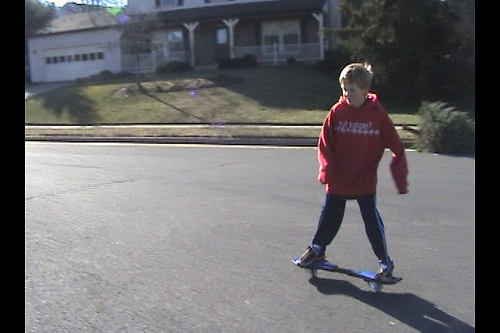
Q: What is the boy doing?
A: Skateboarding.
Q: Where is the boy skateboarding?
A: The road.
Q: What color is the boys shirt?
A: Red.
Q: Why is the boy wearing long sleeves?
A: Its cold.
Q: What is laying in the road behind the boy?
A: A tree.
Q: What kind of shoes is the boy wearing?
A: Sneakers.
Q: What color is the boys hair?
A: Blonde.